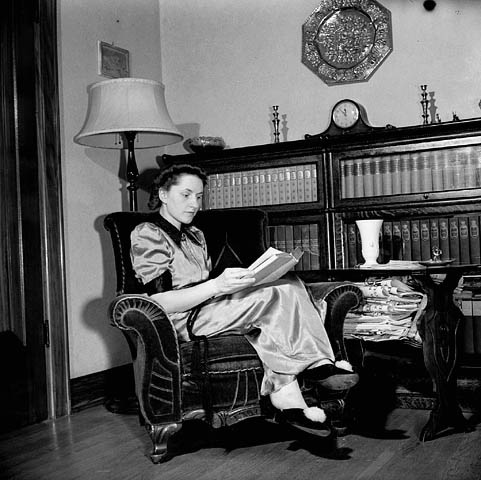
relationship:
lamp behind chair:
[67, 63, 186, 211] [97, 209, 344, 450]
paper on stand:
[334, 243, 456, 449] [339, 255, 466, 451]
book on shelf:
[411, 159, 445, 203] [313, 181, 473, 266]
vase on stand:
[352, 207, 382, 270] [339, 255, 466, 451]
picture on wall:
[87, 26, 153, 78] [165, 35, 303, 118]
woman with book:
[104, 145, 358, 441] [236, 244, 334, 306]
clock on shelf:
[311, 93, 380, 163] [313, 181, 473, 266]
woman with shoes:
[104, 145, 358, 441] [302, 347, 371, 385]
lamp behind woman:
[67, 63, 186, 211] [104, 145, 358, 441]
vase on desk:
[352, 207, 382, 270] [310, 252, 454, 310]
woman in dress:
[104, 145, 358, 441] [147, 251, 337, 400]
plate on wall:
[289, 0, 389, 89] [165, 35, 303, 118]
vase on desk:
[352, 207, 382, 270] [294, 266, 473, 441]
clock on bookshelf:
[311, 93, 380, 163] [136, 166, 465, 356]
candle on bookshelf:
[416, 85, 457, 155] [136, 166, 465, 356]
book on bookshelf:
[411, 159, 445, 203] [136, 166, 465, 356]